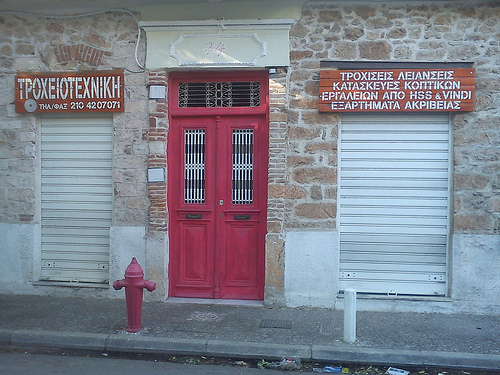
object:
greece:
[0, 0, 499, 375]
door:
[163, 65, 273, 303]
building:
[0, 0, 498, 317]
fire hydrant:
[113, 257, 160, 337]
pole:
[340, 288, 360, 343]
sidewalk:
[0, 282, 500, 372]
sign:
[317, 69, 474, 113]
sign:
[16, 71, 126, 116]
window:
[332, 110, 460, 304]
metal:
[338, 112, 452, 300]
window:
[28, 112, 117, 295]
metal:
[40, 115, 108, 287]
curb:
[0, 323, 499, 374]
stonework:
[0, 0, 499, 236]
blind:
[226, 127, 254, 205]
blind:
[183, 127, 208, 208]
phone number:
[69, 101, 123, 111]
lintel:
[138, 14, 298, 75]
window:
[175, 81, 261, 111]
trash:
[239, 359, 470, 375]